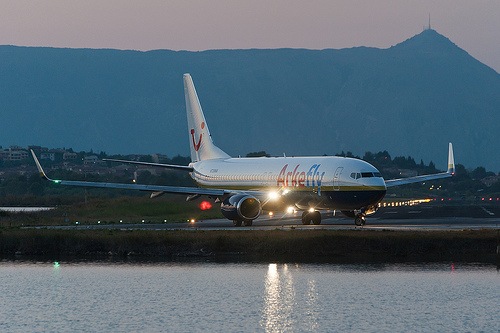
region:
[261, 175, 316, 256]
the light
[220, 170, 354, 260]
the light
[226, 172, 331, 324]
the light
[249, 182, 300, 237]
the light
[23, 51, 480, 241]
A large plane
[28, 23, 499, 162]
A mountain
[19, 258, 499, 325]
A body of water next to the runway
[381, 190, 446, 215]
Runway lights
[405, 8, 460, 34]
tower on top of the mountain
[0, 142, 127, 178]
An urban area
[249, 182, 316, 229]
headlights on the plane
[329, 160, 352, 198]
the entry door on the plane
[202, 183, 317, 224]
the right wing engine on the plane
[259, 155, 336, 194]
The airline brand mark on the plane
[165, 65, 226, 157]
Tail on plane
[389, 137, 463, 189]
Wing on a plane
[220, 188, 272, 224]
Engine on a plane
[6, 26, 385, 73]
Mountain in the distance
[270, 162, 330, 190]
Name of airline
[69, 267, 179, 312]
Water near runway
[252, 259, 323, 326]
Reflection of plane lights on water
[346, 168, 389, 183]
Windows on front of plane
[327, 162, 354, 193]
Door on side of plane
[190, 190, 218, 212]
Red light on plane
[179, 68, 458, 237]
jet airplane on runway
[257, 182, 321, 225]
bright lights on jet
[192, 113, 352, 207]
white, blue and red plane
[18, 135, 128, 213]
wing tips turned upwards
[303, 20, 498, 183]
mountain behind jet plane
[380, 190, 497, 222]
guidance lights on runway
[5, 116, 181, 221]
buildings behind airport runway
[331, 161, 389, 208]
cockpit windows and exit door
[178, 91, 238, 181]
Arkefly Airlines logo on tail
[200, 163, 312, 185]
passenger windows on airplane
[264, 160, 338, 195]
Arkefly on the side of the plane.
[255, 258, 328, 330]
Light reflecting on the water.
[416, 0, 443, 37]
Antenna on top of a mountain.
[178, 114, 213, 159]
Red logo on the plane.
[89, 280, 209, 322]
The water is grey.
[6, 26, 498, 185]
Mountain in the background.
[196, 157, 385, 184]
The top of the plane is silver.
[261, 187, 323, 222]
Lights shining on the plane.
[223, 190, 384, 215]
Bottom of the plane is blue.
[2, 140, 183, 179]
Buildings in the background.